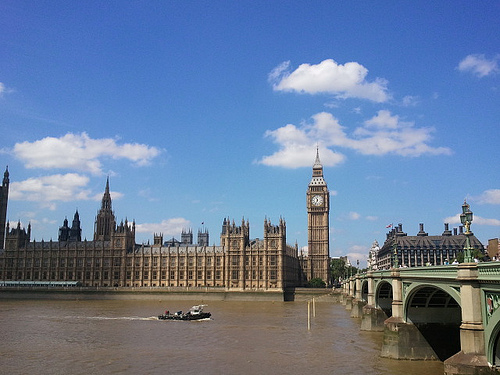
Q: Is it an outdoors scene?
A: Yes, it is outdoors.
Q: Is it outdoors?
A: Yes, it is outdoors.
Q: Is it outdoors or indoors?
A: It is outdoors.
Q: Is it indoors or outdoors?
A: It is outdoors.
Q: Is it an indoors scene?
A: No, it is outdoors.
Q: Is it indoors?
A: No, it is outdoors.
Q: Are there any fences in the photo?
A: No, there are no fences.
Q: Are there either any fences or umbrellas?
A: No, there are no fences or umbrellas.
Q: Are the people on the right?
A: Yes, the people are on the right of the image.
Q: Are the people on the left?
A: No, the people are on the right of the image.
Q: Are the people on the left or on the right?
A: The people are on the right of the image.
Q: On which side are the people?
A: The people are on the right of the image.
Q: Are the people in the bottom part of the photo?
A: Yes, the people are in the bottom of the image.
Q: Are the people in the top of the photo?
A: No, the people are in the bottom of the image.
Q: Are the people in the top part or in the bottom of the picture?
A: The people are in the bottom of the image.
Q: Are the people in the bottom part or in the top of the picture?
A: The people are in the bottom of the image.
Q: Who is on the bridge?
A: The people are on the bridge.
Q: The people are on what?
A: The people are on the bridge.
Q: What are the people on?
A: The people are on the bridge.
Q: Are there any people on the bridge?
A: Yes, there are people on the bridge.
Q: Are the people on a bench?
A: No, the people are on the bridge.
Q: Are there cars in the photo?
A: No, there are no cars.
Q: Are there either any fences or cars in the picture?
A: No, there are no cars or fences.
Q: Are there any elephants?
A: No, there are no elephants.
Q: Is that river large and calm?
A: Yes, the river is large and calm.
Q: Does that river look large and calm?
A: Yes, the river is large and calm.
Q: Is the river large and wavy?
A: No, the river is large but calm.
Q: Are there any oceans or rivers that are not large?
A: No, there is a river but it is large.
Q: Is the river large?
A: Yes, the river is large.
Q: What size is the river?
A: The river is large.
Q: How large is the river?
A: The river is large.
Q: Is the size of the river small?
A: No, the river is large.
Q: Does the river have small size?
A: No, the river is large.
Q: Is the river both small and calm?
A: No, the river is calm but large.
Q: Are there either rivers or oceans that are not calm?
A: No, there is a river but it is calm.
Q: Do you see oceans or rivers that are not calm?
A: No, there is a river but it is calm.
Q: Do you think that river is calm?
A: Yes, the river is calm.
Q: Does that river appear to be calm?
A: Yes, the river is calm.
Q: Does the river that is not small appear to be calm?
A: Yes, the river is calm.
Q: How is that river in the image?
A: The river is calm.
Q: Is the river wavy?
A: No, the river is calm.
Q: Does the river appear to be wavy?
A: No, the river is calm.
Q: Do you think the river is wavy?
A: No, the river is calm.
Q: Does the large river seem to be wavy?
A: No, the river is calm.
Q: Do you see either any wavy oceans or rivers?
A: No, there is a river but it is calm.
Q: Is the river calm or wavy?
A: The river is calm.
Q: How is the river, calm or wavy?
A: The river is calm.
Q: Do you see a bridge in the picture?
A: Yes, there is a bridge.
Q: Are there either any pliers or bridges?
A: Yes, there is a bridge.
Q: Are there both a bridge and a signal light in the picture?
A: No, there is a bridge but no traffic lights.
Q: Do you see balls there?
A: No, there are no balls.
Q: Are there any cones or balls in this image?
A: No, there are no balls or cones.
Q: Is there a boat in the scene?
A: Yes, there is a boat.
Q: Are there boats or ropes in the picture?
A: Yes, there is a boat.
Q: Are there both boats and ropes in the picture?
A: No, there is a boat but no ropes.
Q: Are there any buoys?
A: No, there are no buoys.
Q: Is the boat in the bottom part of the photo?
A: Yes, the boat is in the bottom of the image.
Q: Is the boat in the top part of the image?
A: No, the boat is in the bottom of the image.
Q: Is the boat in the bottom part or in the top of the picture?
A: The boat is in the bottom of the image.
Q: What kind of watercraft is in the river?
A: The watercraft is a boat.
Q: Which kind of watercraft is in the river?
A: The watercraft is a boat.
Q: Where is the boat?
A: The boat is in the river.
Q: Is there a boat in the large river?
A: Yes, there is a boat in the river.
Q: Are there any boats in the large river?
A: Yes, there is a boat in the river.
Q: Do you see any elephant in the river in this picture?
A: No, there is a boat in the river.